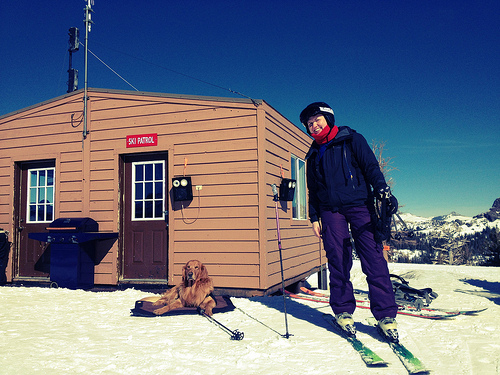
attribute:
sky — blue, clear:
[0, 1, 499, 218]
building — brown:
[5, 83, 326, 301]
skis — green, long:
[323, 306, 432, 373]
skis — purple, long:
[288, 280, 489, 321]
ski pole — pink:
[272, 190, 294, 341]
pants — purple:
[315, 206, 398, 320]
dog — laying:
[141, 258, 215, 317]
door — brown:
[118, 158, 167, 282]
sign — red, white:
[125, 132, 160, 149]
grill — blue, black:
[28, 219, 119, 293]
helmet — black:
[296, 99, 335, 129]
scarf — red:
[308, 126, 336, 145]